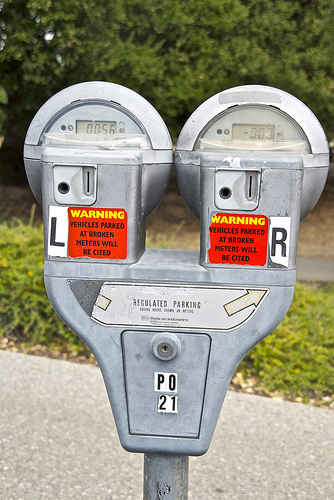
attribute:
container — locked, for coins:
[41, 250, 296, 455]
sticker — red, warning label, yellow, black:
[66, 207, 128, 262]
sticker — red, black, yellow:
[206, 210, 268, 267]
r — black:
[272, 227, 285, 258]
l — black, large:
[50, 216, 65, 248]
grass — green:
[1, 224, 83, 349]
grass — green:
[239, 282, 333, 397]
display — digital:
[76, 120, 118, 134]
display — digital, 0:
[230, 124, 275, 141]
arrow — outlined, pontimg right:
[223, 290, 268, 317]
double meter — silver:
[24, 81, 330, 456]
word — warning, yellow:
[69, 209, 127, 221]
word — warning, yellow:
[212, 214, 267, 228]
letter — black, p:
[156, 373, 165, 393]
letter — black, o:
[169, 375, 177, 391]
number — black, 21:
[158, 394, 176, 412]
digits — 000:
[249, 127, 265, 142]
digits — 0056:
[86, 122, 116, 134]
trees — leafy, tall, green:
[0, 2, 332, 155]